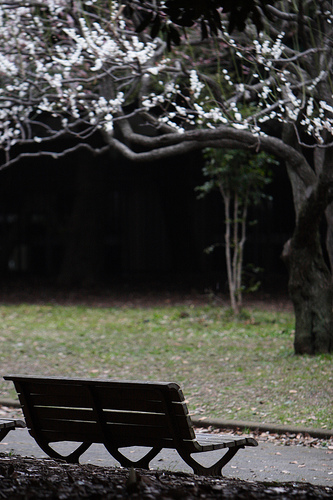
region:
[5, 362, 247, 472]
wooden bench on park trail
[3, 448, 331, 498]
rock wall behind bench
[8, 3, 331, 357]
tree with white blooms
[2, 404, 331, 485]
pathway in front of bench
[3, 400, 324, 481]
fallen leaves on pathway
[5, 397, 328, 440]
curb of pathway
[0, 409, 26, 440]
edge of park bench on left side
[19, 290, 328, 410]
grassy area on other side of path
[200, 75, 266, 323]
small tree beside large tree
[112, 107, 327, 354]
brown tree trunk and branches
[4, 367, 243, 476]
Brown wooden bench outside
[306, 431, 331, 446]
Leaves on the pavement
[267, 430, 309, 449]
Leaves on the pavement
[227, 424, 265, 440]
Leaves on the pavement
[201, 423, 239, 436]
Leaves on the pavement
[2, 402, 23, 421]
Leaves on the pavement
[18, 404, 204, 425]
Dark wooden slat on bench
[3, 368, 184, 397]
Dark wooden slat on bench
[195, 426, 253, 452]
Dark wooden slat on bench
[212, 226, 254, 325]
Small brown tree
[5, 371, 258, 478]
brown wooden bench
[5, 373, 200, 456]
backplate of bench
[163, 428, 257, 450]
seat of bench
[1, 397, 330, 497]
path in a park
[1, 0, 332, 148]
white flowers on big tree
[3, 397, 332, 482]
a bunch of dry leaves in a path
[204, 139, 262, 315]
small thin tree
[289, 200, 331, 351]
thicke stem of big tree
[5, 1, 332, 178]
big branches of big tree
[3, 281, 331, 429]
small green grass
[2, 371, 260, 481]
the bench on a pathway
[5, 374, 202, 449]
the back of a bench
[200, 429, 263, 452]
the seat of a bench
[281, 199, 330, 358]
a trunk of a tree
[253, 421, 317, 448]
the cement curb on a walkway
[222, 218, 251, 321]
the trunks of a trees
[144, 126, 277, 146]
a limb of a tree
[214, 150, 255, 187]
the leaves of a tree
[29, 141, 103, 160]
a branch of a tree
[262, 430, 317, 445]
the dried leaves at the edge of a pathway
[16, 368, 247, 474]
a wooden bench on a sidewalk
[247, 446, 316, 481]
black asphalt of the path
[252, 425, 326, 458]
fallen leaves on the path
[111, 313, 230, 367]
green grass of the park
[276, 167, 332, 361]
large tree trunk in the courtyard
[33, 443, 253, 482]
metal legs of the bench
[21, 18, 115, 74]
grey cloudy skies over the park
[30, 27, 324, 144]
purple and white blossoms on the tree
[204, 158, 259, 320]
a young tree growing in the courtyard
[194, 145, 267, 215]
green leaves of the young tree